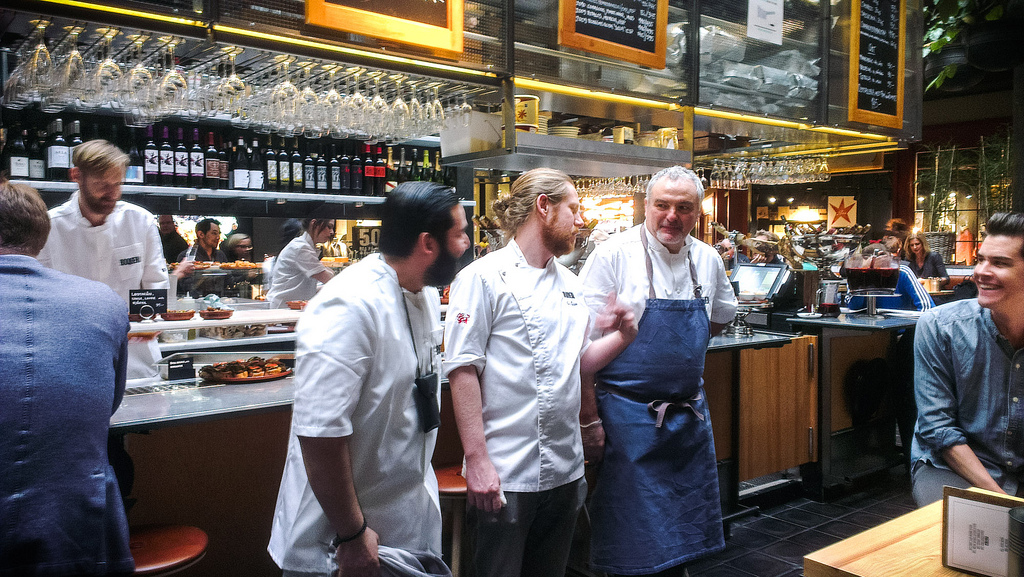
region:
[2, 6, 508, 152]
Row of wine glasses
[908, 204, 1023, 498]
Young man laughing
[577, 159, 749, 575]
Man in a blue apron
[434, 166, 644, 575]
Man wearing white chef coat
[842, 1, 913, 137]
Sign in a wooden frame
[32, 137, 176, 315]
Man in white chef coat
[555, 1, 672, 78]
Sign in wooden frame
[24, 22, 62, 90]
a vessel made for drinking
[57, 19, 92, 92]
a vessel made for drinking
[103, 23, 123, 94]
a vessel made for drinking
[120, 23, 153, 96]
a vessel made for drinking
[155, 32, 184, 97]
a vessel made for drinking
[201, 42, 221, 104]
a vessel made for drinking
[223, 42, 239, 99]
a vessel made for drinking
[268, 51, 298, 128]
a vessel made for drinking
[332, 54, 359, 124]
a vessel made for drinking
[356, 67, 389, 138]
a vessel made for drinking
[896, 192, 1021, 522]
man in blue shirt at table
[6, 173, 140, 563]
man in blue shirt at bar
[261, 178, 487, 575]
dark haired man in chef coat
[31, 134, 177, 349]
chef working behind the bar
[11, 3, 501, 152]
glasses hanging overhead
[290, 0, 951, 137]
chalkboards with writing on them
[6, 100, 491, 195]
row of alcohol bottles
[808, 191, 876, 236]
red star on yellow background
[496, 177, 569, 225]
a man with blonde hair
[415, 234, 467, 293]
a man with a beard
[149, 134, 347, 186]
a row of bottles on a shelf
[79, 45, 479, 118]
several glasses hanging from a rack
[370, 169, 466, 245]
a man with black hair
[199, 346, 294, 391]
a tray of food on a counter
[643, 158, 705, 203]
a man with grey hair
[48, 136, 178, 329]
man behind the counter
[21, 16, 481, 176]
wineglasses hanging from the bar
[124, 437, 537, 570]
stools at the bar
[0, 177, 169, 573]
man wearing blue coat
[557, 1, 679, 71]
chalkboard with wood frame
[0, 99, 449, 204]
wine bottles in a row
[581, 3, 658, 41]
white writing on chalkboard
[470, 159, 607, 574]
man wearing gray pants